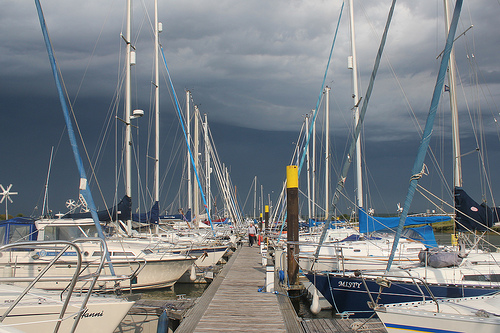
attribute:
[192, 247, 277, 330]
pier — long, wooden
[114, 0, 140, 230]
mast — tall, white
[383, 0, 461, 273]
sail — light blue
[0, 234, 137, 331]
boat — many, docking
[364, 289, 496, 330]
boat — white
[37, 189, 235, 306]
boats — leisure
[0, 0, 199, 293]
boats — for cruising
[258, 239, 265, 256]
post — white, small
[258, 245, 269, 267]
post — white, small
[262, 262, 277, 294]
post — white, small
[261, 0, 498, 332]
boats — for fishing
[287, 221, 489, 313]
boat — blue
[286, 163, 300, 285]
post — wooden, brown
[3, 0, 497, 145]
cloud — white, grey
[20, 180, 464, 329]
docks — commercial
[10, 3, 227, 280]
boat — leisure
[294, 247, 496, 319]
boat — dark blue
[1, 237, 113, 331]
hand rail — silver, metal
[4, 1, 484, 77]
cloud — blue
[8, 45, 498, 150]
cloud — blue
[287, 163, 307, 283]
post — yellow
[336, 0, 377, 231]
pole — silver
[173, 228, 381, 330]
pier — wooden